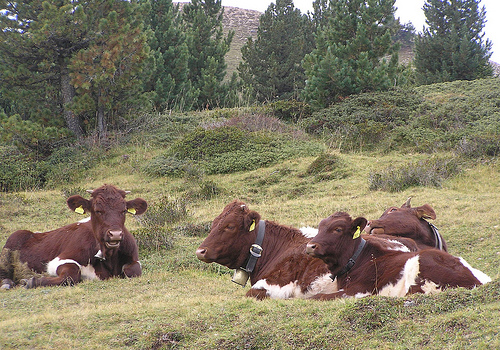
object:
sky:
[176, 0, 500, 60]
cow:
[0, 185, 147, 289]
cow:
[194, 202, 343, 291]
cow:
[310, 211, 493, 302]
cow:
[243, 196, 446, 298]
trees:
[59, 2, 127, 150]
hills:
[141, 79, 490, 133]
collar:
[246, 216, 267, 271]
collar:
[331, 237, 367, 279]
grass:
[0, 152, 500, 350]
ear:
[350, 217, 367, 230]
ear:
[242, 211, 261, 230]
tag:
[74, 205, 85, 214]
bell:
[232, 266, 249, 285]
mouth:
[106, 233, 122, 247]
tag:
[353, 225, 360, 239]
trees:
[414, 1, 494, 86]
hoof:
[23, 275, 36, 289]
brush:
[366, 157, 465, 191]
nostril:
[201, 249, 207, 254]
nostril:
[311, 244, 316, 248]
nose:
[108, 231, 114, 237]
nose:
[367, 223, 371, 226]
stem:
[36, 141, 39, 160]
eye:
[335, 228, 342, 232]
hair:
[41, 261, 57, 266]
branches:
[9, 51, 52, 61]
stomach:
[22, 258, 60, 276]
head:
[195, 201, 259, 273]